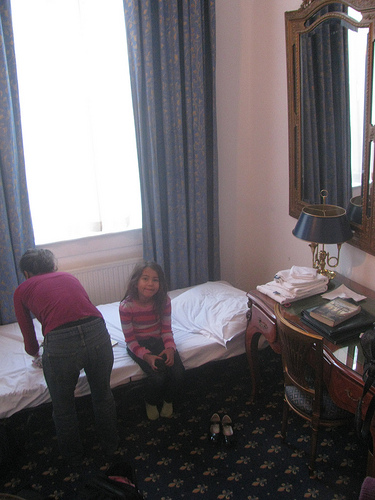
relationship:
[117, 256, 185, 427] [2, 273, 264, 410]
girl sitting on sheets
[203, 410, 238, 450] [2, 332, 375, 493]
shoes sitting on floor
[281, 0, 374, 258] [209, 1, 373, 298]
mirror on wall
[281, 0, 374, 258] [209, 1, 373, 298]
mirror hanging on wall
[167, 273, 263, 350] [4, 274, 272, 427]
pillow on bed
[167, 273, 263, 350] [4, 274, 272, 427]
pillow sitting on bed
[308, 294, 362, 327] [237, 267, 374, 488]
book laying on desk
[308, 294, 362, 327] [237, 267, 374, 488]
book on desk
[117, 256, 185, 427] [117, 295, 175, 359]
girl in shirt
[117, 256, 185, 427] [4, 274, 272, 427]
girl sitting on bed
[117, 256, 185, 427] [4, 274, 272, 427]
girl on bed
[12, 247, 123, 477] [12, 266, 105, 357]
woman in shirt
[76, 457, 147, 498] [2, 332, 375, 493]
bag on floor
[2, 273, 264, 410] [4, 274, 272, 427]
sheets on bed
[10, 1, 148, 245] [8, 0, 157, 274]
light through window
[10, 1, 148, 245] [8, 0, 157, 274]
light shining through window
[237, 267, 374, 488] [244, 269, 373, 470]
desk made of wood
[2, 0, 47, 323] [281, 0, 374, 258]
curtain into mirror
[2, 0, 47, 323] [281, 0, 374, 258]
curtain reflecting into mirror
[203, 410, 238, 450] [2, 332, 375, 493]
shoes on floor